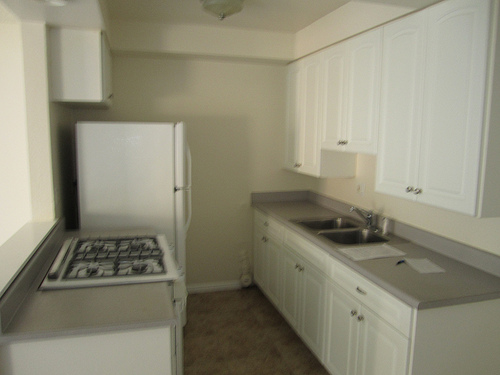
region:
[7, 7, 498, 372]
white cabinets are in the kitchen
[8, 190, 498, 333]
the countertops and backsplash are gray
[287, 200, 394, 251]
the kitchen has a double sink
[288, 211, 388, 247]
the double sink is stainless steel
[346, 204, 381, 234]
the sink has a chrome faucet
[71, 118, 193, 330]
the white refridgerator has a freezer on top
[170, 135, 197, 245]
the refridgerator has white handles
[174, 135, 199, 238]
the handles are on the left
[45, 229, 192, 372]
the gas stove is white with black grates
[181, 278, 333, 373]
the floor is tiled in beige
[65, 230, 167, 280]
Ranges on stove top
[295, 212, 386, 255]
Sinks in counter top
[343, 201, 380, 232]
Metal faucet on sink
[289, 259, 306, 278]
Handles on kitchen cabinets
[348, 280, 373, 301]
Handle on kitchen drawer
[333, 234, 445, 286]
Papers on kitchen counter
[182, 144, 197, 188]
White handle on freezer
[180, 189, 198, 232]
White handle on fridge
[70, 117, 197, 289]
White fridge and freezer combo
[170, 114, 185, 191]
White freezer door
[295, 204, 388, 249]
Chrome double sink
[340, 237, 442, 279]
Two pieces of paper on the countertop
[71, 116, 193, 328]
White refrigerator in the corner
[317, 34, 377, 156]
White cabinets over sink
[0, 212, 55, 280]
Ledge of window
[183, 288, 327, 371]
Tiling on the floor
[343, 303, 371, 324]
Silver knobs on cabinet doors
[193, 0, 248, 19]
Lamp in the ceiling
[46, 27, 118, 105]
White cabinet over refrigerator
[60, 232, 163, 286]
Four-burner stovetop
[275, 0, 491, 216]
the hanging cabinets are white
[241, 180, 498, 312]
the counter top is grey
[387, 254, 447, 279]
paper and a pen are on the counter top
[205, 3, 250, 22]
a light is hanging from the ceiling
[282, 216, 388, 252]
the sink is stainless steel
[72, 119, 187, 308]
the fridge is white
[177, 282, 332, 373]
the floor is tan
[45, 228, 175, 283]
the stove top is black and white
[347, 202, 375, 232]
the faucet is silver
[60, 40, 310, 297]
the back wall is beige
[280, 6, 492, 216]
white cabinets on wall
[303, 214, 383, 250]
two sinks in counter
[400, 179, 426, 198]
metal knobs on doors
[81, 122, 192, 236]
side of white refrigerator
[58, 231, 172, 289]
four burners on stove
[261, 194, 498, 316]
gray kitchen counter against wall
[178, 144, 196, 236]
handles on freezer and fridge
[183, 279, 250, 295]
white molding on wall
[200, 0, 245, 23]
light on kitchen ceiling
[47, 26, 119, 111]
side of cupboard on ceiling